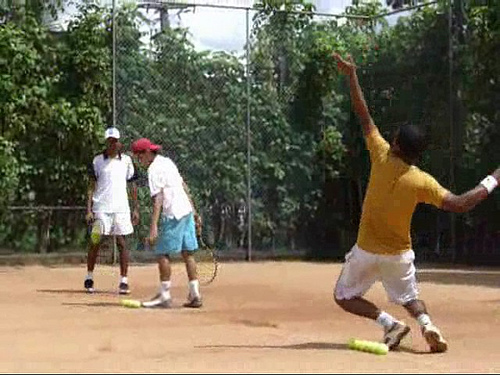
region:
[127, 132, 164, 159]
red cap worn backwards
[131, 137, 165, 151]
red cap worn backwards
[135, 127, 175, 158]
red cap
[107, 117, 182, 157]
red cap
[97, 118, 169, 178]
red cap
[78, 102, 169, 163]
red cap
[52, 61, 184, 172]
red cap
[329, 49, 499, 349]
man in yellow shirt serving the ball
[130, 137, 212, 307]
man standing in red cap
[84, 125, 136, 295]
man wearing white cap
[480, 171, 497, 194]
white sweat band on arm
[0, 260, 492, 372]
clay tennis court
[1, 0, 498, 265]
tall fence around court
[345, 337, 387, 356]
long line of tennis balls in front of player serving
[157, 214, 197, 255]
blue shorts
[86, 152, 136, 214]
white shirt with black trim on the sleeves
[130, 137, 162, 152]
red cap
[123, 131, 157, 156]
the red color cap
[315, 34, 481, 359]
the man playing tennis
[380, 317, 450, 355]
a pair of white shoes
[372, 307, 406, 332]
the white color socks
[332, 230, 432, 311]
the white color shorts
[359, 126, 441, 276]
the yellow color t shirt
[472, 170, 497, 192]
the white color wrist band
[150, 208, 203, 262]
the blue color short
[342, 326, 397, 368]
the radium color tennis balls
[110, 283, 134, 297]
the black color shoes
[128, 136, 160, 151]
man wearing red hat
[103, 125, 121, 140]
man wearing white hat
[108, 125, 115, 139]
blue symbol on hat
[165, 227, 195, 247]
man wearing blue shorts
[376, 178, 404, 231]
man wearing yellow shirt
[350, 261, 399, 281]
man wearing white shorts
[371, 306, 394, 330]
man wearing white socks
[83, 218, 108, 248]
black tennis racket in mans hand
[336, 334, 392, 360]
green tennis balls on court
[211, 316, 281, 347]
pinkish floor of court